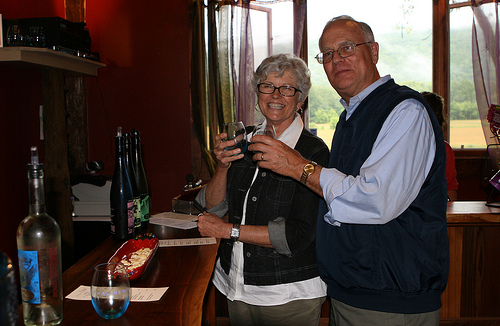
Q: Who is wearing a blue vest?
A: The man.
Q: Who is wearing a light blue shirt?
A: The older man.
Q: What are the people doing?
A: Making a toast with a drink.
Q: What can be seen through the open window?
A: Mountains and fields.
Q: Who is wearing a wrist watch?
A: Both people.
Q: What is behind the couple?
A: Open window.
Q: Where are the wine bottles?
A: On the table top.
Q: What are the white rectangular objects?
A: Pieces of paper.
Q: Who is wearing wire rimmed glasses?
A: The man.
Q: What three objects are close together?
A: Wine bottles.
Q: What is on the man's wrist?
A: A watch.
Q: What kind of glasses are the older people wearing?
A: Eyeglasses.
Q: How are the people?
A: Happy.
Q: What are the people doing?
A: Posing for a picture.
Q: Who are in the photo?
A: A couple.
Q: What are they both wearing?
A: Glasses.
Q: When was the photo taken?
A: Daytime.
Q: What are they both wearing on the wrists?
A: Watches.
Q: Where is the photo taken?
A: A kitchen.